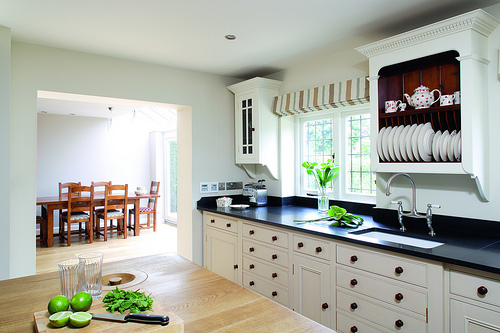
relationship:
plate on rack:
[418, 122, 436, 162] [377, 108, 464, 163]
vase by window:
[315, 183, 331, 216] [293, 100, 378, 205]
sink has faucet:
[346, 226, 447, 251] [374, 172, 443, 224]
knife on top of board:
[87, 311, 171, 327] [31, 288, 188, 333]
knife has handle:
[87, 311, 171, 327] [123, 310, 171, 326]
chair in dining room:
[59, 182, 96, 245] [32, 96, 181, 276]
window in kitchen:
[293, 100, 378, 205] [0, 1, 500, 332]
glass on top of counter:
[59, 257, 84, 303] [0, 250, 337, 331]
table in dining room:
[36, 190, 162, 247] [32, 96, 181, 276]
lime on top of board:
[70, 290, 94, 311] [31, 288, 188, 333]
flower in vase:
[303, 153, 341, 190] [315, 183, 331, 216]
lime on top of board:
[48, 310, 94, 329] [31, 288, 188, 333]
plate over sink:
[418, 122, 436, 162] [346, 226, 447, 251]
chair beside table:
[59, 182, 96, 245] [36, 190, 162, 247]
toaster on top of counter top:
[243, 181, 270, 206] [194, 200, 499, 276]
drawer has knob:
[334, 243, 431, 288] [351, 254, 359, 262]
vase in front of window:
[315, 183, 331, 216] [293, 100, 378, 205]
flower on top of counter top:
[303, 153, 341, 190] [194, 200, 499, 276]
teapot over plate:
[404, 84, 442, 112] [418, 122, 436, 162]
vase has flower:
[315, 183, 331, 216] [303, 153, 341, 190]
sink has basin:
[346, 226, 447, 251] [358, 232, 443, 250]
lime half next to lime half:
[67, 309, 92, 329] [45, 309, 74, 327]